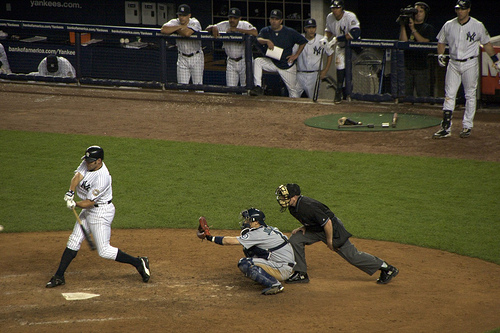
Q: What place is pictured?
A: It is a field.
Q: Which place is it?
A: It is a field.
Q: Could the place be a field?
A: Yes, it is a field.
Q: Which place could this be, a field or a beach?
A: It is a field.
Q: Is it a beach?
A: No, it is a field.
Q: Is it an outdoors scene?
A: Yes, it is outdoors.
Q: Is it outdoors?
A: Yes, it is outdoors.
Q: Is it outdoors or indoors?
A: It is outdoors.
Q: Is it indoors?
A: No, it is outdoors.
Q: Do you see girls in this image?
A: No, there are no girls.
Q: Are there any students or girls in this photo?
A: No, there are no girls or students.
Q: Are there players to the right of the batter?
A: Yes, there is a player to the right of the batter.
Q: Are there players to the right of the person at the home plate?
A: Yes, there is a player to the right of the batter.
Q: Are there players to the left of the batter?
A: No, the player is to the right of the batter.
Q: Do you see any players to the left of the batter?
A: No, the player is to the right of the batter.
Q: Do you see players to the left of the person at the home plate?
A: No, the player is to the right of the batter.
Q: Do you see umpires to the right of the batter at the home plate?
A: No, there is a player to the right of the batter.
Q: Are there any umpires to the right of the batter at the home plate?
A: No, there is a player to the right of the batter.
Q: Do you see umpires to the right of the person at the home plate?
A: No, there is a player to the right of the batter.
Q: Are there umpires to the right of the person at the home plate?
A: No, there is a player to the right of the batter.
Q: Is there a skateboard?
A: No, there are no skateboards.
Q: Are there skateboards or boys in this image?
A: No, there are no skateboards or boys.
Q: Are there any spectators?
A: No, there are no spectators.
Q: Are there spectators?
A: No, there are no spectators.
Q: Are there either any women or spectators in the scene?
A: No, there are no spectators or women.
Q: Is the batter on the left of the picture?
A: Yes, the batter is on the left of the image.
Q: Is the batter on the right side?
A: No, the batter is on the left of the image.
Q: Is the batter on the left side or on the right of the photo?
A: The batter is on the left of the image.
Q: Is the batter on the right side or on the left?
A: The batter is on the left of the image.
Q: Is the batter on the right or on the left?
A: The batter is on the left of the image.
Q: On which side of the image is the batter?
A: The batter is on the left of the image.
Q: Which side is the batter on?
A: The batter is on the left of the image.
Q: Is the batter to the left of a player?
A: Yes, the batter is to the left of a player.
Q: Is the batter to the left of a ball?
A: No, the batter is to the left of a player.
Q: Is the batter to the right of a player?
A: No, the batter is to the left of a player.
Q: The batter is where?
A: The batter is at the home plate.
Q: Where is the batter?
A: The batter is at the home plate.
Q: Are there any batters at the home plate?
A: Yes, there is a batter at the home plate.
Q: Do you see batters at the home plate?
A: Yes, there is a batter at the home plate.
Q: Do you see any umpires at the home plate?
A: No, there is a batter at the home plate.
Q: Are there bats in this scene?
A: Yes, there is a bat.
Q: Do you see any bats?
A: Yes, there is a bat.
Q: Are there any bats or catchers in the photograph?
A: Yes, there is a bat.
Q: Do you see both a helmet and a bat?
A: Yes, there are both a bat and a helmet.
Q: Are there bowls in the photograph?
A: No, there are no bowls.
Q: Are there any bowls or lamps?
A: No, there are no bowls or lamps.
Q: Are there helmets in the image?
A: Yes, there is a helmet.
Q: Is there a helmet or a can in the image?
A: Yes, there is a helmet.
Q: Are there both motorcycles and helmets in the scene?
A: No, there is a helmet but no motorcycles.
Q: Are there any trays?
A: No, there are no trays.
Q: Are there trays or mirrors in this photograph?
A: No, there are no trays or mirrors.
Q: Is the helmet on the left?
A: Yes, the helmet is on the left of the image.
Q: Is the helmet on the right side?
A: No, the helmet is on the left of the image.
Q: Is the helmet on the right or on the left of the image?
A: The helmet is on the left of the image.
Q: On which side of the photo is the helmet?
A: The helmet is on the left of the image.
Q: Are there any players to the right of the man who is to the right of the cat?
A: Yes, there is a player to the right of the man.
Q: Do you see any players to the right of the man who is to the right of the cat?
A: Yes, there is a player to the right of the man.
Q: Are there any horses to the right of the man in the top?
A: No, there is a player to the right of the man.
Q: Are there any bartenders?
A: No, there are no bartenders.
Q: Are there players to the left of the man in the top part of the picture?
A: Yes, there is a player to the left of the man.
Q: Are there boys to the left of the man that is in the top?
A: No, there is a player to the left of the man.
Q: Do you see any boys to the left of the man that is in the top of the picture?
A: No, there is a player to the left of the man.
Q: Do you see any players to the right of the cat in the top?
A: Yes, there is a player to the right of the cat.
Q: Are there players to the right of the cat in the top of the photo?
A: Yes, there is a player to the right of the cat.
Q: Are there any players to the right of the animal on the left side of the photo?
A: Yes, there is a player to the right of the cat.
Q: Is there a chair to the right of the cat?
A: No, there is a player to the right of the cat.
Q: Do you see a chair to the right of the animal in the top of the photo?
A: No, there is a player to the right of the cat.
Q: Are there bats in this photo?
A: Yes, there is a bat.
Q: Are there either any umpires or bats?
A: Yes, there is a bat.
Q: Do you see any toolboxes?
A: No, there are no toolboxes.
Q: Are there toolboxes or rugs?
A: No, there are no toolboxes or rugs.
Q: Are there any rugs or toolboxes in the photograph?
A: No, there are no toolboxes or rugs.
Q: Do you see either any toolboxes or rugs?
A: No, there are no toolboxes or rugs.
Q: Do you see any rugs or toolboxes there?
A: No, there are no toolboxes or rugs.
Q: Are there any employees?
A: No, there are no employees.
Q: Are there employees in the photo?
A: No, there are no employees.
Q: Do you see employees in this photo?
A: No, there are no employees.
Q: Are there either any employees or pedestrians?
A: No, there are no employees or pedestrians.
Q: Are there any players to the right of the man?
A: Yes, there is a player to the right of the man.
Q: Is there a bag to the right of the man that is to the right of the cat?
A: No, there is a player to the right of the man.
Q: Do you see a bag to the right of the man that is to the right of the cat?
A: No, there is a player to the right of the man.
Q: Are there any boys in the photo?
A: No, there are no boys.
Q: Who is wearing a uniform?
A: The player is wearing a uniform.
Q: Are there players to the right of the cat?
A: Yes, there is a player to the right of the cat.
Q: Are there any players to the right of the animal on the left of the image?
A: Yes, there is a player to the right of the cat.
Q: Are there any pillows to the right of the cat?
A: No, there is a player to the right of the cat.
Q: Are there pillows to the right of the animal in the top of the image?
A: No, there is a player to the right of the cat.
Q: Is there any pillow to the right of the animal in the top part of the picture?
A: No, there is a player to the right of the cat.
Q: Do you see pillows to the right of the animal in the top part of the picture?
A: No, there is a player to the right of the cat.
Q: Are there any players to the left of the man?
A: Yes, there is a player to the left of the man.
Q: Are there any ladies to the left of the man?
A: No, there is a player to the left of the man.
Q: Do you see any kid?
A: No, there are no children.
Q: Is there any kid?
A: No, there are no children.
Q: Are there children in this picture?
A: No, there are no children.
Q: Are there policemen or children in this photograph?
A: No, there are no children or policemen.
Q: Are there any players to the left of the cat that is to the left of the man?
A: Yes, there is a player to the left of the cat.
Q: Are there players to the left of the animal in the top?
A: Yes, there is a player to the left of the cat.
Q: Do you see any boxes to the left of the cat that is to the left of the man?
A: No, there is a player to the left of the cat.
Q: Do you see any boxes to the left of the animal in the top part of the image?
A: No, there is a player to the left of the cat.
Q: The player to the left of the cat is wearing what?
A: The player is wearing a uniform.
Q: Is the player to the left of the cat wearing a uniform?
A: Yes, the player is wearing a uniform.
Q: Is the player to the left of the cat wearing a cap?
A: No, the player is wearing a uniform.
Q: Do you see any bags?
A: No, there are no bags.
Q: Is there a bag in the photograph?
A: No, there are no bags.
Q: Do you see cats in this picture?
A: Yes, there is a cat.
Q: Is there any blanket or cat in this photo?
A: Yes, there is a cat.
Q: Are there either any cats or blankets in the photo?
A: Yes, there is a cat.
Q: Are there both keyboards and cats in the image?
A: No, there is a cat but no keyboards.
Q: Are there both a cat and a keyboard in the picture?
A: No, there is a cat but no keyboards.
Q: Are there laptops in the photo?
A: No, there are no laptops.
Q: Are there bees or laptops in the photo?
A: No, there are no laptops or bees.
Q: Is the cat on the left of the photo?
A: Yes, the cat is on the left of the image.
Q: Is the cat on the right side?
A: No, the cat is on the left of the image.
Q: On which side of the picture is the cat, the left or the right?
A: The cat is on the left of the image.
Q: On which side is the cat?
A: The cat is on the left of the image.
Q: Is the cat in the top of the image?
A: Yes, the cat is in the top of the image.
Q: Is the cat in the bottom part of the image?
A: No, the cat is in the top of the image.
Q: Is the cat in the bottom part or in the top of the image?
A: The cat is in the top of the image.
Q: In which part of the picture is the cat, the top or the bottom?
A: The cat is in the top of the image.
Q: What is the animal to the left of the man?
A: The animal is a cat.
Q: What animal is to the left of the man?
A: The animal is a cat.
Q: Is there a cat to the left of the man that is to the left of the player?
A: Yes, there is a cat to the left of the man.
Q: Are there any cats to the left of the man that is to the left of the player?
A: Yes, there is a cat to the left of the man.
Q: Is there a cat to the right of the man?
A: No, the cat is to the left of the man.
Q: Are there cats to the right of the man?
A: No, the cat is to the left of the man.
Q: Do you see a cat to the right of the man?
A: No, the cat is to the left of the man.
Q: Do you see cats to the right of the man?
A: No, the cat is to the left of the man.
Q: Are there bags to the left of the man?
A: No, there is a cat to the left of the man.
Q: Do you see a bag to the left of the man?
A: No, there is a cat to the left of the man.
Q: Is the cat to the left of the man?
A: Yes, the cat is to the left of the man.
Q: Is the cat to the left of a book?
A: No, the cat is to the left of the man.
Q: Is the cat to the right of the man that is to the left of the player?
A: No, the cat is to the left of the man.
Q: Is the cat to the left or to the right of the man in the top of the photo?
A: The cat is to the left of the man.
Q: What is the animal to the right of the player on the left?
A: The animal is a cat.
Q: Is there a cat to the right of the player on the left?
A: Yes, there is a cat to the right of the player.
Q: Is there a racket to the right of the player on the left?
A: No, there is a cat to the right of the player.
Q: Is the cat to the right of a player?
A: Yes, the cat is to the right of a player.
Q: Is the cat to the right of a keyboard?
A: No, the cat is to the right of a player.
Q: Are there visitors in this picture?
A: No, there are no visitors.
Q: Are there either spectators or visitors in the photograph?
A: No, there are no visitors or spectators.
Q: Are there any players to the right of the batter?
A: Yes, there is a player to the right of the batter.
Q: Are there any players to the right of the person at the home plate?
A: Yes, there is a player to the right of the batter.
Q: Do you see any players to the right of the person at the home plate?
A: Yes, there is a player to the right of the batter.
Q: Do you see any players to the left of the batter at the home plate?
A: No, the player is to the right of the batter.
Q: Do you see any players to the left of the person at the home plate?
A: No, the player is to the right of the batter.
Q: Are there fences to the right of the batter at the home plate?
A: No, there is a player to the right of the batter.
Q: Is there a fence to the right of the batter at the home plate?
A: No, there is a player to the right of the batter.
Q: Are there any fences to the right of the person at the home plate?
A: No, there is a player to the right of the batter.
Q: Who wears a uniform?
A: The player wears a uniform.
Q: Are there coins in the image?
A: No, there are no coins.